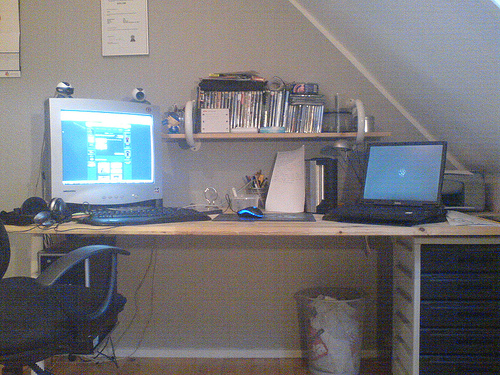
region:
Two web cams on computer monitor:
[54, 79, 156, 145]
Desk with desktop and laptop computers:
[41, 93, 459, 237]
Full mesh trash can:
[290, 284, 379, 373]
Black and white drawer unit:
[388, 235, 499, 369]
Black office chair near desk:
[0, 207, 135, 366]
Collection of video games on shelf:
[181, 84, 354, 133]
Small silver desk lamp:
[328, 132, 367, 171]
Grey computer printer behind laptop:
[428, 167, 491, 223]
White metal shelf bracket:
[173, 96, 205, 157]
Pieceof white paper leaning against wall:
[258, 142, 322, 218]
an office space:
[3, 3, 486, 368]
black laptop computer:
[331, 135, 449, 231]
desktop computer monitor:
[45, 98, 165, 210]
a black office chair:
[0, 224, 127, 364]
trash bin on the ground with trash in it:
[284, 277, 373, 374]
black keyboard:
[86, 197, 211, 232]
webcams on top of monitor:
[47, 79, 162, 154]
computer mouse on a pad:
[216, 201, 317, 226]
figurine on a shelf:
[156, 102, 192, 143]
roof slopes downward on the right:
[267, 0, 499, 210]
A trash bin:
[281, 280, 341, 337]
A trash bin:
[317, 282, 353, 340]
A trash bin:
[311, 288, 374, 350]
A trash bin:
[341, 293, 376, 369]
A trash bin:
[290, 227, 347, 372]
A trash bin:
[317, 322, 338, 367]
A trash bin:
[328, 276, 406, 373]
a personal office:
[6, 11, 498, 367]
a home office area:
[4, 14, 497, 370]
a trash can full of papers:
[289, 282, 379, 373]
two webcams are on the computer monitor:
[45, 80, 161, 110]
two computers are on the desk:
[32, 81, 454, 231]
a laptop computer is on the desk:
[332, 133, 454, 223]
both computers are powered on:
[41, 89, 461, 228]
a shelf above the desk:
[162, 74, 388, 152]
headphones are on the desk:
[14, 192, 86, 224]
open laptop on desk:
[329, 134, 468, 242]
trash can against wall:
[285, 282, 372, 374]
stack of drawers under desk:
[407, 229, 497, 366]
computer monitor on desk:
[55, 96, 167, 210]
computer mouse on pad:
[223, 200, 266, 226]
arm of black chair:
[35, 239, 131, 321]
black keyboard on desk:
[81, 202, 226, 238]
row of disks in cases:
[185, 90, 329, 145]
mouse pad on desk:
[265, 210, 319, 231]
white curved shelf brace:
[177, 99, 200, 160]